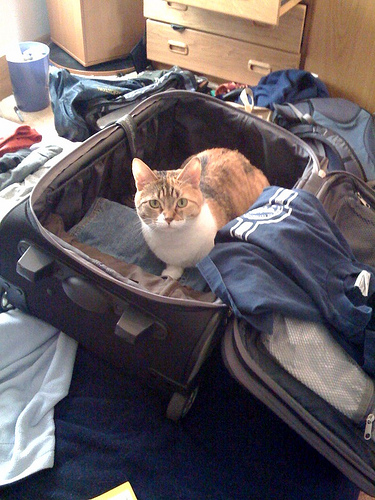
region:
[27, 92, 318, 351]
cat in a suitcase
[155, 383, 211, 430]
wheel on the bottom of the suitcase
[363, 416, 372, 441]
small silver zipper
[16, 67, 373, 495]
suitcase is hanging open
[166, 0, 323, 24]
drawer is open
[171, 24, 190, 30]
article of clothing hanging out of the drawer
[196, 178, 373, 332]
shirt laying in the suitcase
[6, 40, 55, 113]
small trash can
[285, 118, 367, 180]
thick strap on the bag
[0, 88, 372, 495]
suitcase laying on the bed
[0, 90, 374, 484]
cat laying in a suitcase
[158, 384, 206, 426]
small wheel on the bottom of the suitcase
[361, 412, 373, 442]
small silver zipper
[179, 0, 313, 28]
drawer is open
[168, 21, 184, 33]
article of clothing sticking out of the drawer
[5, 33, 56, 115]
small trash can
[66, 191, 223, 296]
jeans folded in the suitcase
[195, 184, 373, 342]
shirt in the suitcase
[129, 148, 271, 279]
A brown and white cat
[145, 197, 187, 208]
cat has green eyes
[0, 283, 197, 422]
wheels of suitcase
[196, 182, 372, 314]
a blue t shirt with white graphic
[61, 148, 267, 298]
cat is laying on top of jeans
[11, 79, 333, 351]
cat is inside suitcase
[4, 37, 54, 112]
a small blue waste paper basket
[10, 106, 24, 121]
a black marker pen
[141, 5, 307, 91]
light tan chest of drawers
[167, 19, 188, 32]
a piece of clothing sticking out of drawer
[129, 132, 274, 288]
cat in a suitcase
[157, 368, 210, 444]
wheel on a suitcase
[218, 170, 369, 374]
blue t-shirt by a suitcase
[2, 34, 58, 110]
trash can in a room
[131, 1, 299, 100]
drawers to a bureau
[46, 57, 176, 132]
clothes on the floor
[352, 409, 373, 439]
zipper on a suitcase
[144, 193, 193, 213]
eyes of a cat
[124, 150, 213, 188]
ears of a cat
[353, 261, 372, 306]
tag on a t-shirt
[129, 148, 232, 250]
the head of a cat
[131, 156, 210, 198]
the ear of a cat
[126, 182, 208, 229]
the eyes of a cat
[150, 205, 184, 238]
the nose of a cat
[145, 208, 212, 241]
the mouth of a cat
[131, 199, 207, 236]
the whiskers of a cat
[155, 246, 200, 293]
the paw of a cat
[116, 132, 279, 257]
a white and brown cat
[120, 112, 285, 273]
a cat in a suit case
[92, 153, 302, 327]
a shirt near a cat